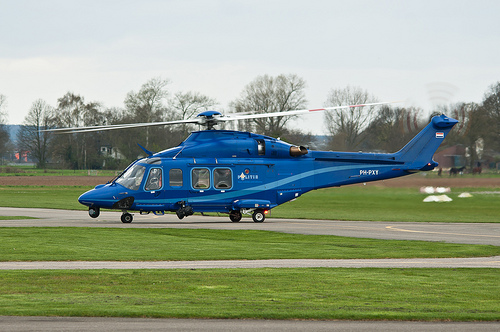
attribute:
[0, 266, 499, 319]
grass — green, short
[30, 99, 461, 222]
helicopter — blue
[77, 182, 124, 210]
tip — metal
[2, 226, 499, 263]
grass — green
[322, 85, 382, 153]
tree — bare, distant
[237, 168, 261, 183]
decal — white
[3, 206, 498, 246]
asphalt — runway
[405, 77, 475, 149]
rotor — in motion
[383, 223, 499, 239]
line — yellow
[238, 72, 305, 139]
tree — distant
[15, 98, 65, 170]
tree — distant